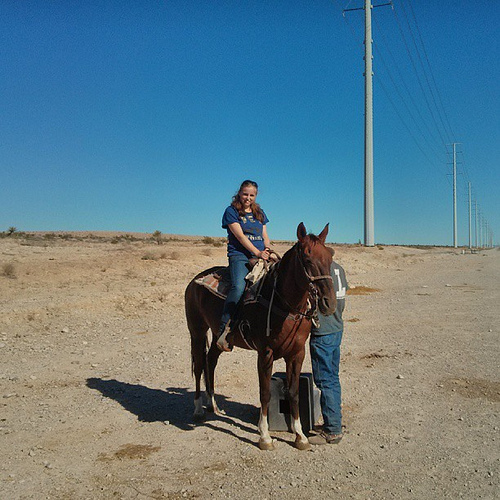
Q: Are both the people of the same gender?
A: No, they are both male and female.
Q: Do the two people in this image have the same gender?
A: No, they are both male and female.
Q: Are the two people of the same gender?
A: No, they are both male and female.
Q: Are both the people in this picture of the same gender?
A: No, they are both male and female.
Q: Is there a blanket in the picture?
A: Yes, there is a blanket.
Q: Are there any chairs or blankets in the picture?
A: Yes, there is a blanket.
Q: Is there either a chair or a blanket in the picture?
A: Yes, there is a blanket.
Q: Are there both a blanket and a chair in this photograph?
A: No, there is a blanket but no chairs.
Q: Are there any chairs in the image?
A: No, there are no chairs.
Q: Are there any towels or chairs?
A: No, there are no chairs or towels.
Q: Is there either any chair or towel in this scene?
A: No, there are no chairs or towels.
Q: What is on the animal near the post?
A: The blanket is on the horse.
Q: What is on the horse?
A: The blanket is on the horse.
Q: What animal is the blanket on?
A: The blanket is on the horse.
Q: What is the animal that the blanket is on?
A: The animal is a horse.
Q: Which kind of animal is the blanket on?
A: The blanket is on the horse.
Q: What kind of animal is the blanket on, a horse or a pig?
A: The blanket is on a horse.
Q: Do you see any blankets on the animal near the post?
A: Yes, there is a blanket on the horse.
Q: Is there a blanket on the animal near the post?
A: Yes, there is a blanket on the horse.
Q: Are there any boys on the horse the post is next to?
A: No, there is a blanket on the horse.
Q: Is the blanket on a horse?
A: Yes, the blanket is on a horse.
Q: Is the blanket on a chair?
A: No, the blanket is on a horse.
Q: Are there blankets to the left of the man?
A: Yes, there is a blanket to the left of the man.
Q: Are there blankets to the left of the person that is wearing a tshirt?
A: Yes, there is a blanket to the left of the man.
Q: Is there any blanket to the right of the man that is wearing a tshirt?
A: No, the blanket is to the left of the man.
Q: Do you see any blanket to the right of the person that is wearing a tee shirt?
A: No, the blanket is to the left of the man.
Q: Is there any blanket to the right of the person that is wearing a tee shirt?
A: No, the blanket is to the left of the man.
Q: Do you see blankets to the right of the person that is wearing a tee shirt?
A: No, the blanket is to the left of the man.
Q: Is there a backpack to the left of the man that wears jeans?
A: No, there is a blanket to the left of the man.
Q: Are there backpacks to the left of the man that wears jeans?
A: No, there is a blanket to the left of the man.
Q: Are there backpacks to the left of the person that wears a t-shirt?
A: No, there is a blanket to the left of the man.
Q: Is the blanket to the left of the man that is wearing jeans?
A: Yes, the blanket is to the left of the man.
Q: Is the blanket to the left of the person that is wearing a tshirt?
A: Yes, the blanket is to the left of the man.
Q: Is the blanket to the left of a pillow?
A: No, the blanket is to the left of the man.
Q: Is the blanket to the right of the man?
A: No, the blanket is to the left of the man.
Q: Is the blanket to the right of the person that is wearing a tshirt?
A: No, the blanket is to the left of the man.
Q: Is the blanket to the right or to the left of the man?
A: The blanket is to the left of the man.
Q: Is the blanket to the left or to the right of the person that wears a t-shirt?
A: The blanket is to the left of the man.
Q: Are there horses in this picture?
A: Yes, there is a horse.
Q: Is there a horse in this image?
A: Yes, there is a horse.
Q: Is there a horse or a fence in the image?
A: Yes, there is a horse.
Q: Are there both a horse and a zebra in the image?
A: No, there is a horse but no zebras.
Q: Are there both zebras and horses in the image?
A: No, there is a horse but no zebras.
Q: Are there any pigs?
A: No, there are no pigs.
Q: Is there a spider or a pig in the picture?
A: No, there are no pigs or spiders.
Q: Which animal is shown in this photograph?
A: The animal is a horse.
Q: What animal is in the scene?
A: The animal is a horse.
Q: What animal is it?
A: The animal is a horse.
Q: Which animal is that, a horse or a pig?
A: That is a horse.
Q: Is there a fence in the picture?
A: No, there are no fences.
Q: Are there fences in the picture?
A: No, there are no fences.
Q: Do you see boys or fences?
A: No, there are no fences or boys.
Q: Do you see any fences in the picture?
A: No, there are no fences.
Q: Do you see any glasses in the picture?
A: No, there are no glasses.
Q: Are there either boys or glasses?
A: No, there are no glasses or boys.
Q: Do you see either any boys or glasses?
A: No, there are no glasses or boys.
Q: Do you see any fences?
A: No, there are no fences.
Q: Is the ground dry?
A: Yes, the ground is dry.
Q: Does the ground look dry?
A: Yes, the ground is dry.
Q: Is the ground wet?
A: No, the ground is dry.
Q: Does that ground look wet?
A: No, the ground is dry.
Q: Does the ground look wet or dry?
A: The ground is dry.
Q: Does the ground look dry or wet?
A: The ground is dry.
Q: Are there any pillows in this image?
A: No, there are no pillows.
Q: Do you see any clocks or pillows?
A: No, there are no pillows or clocks.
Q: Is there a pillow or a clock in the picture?
A: No, there are no pillows or clocks.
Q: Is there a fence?
A: No, there are no fences.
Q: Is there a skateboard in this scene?
A: No, there are no skateboards.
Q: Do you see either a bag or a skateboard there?
A: No, there are no skateboards or bags.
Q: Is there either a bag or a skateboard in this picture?
A: No, there are no skateboards or bags.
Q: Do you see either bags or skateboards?
A: No, there are no skateboards or bags.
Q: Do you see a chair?
A: No, there are no chairs.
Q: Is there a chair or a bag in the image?
A: No, there are no chairs or bags.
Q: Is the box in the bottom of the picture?
A: Yes, the box is in the bottom of the image.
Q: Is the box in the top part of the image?
A: No, the box is in the bottom of the image.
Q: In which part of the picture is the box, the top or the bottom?
A: The box is in the bottom of the image.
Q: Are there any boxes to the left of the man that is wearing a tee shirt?
A: Yes, there is a box to the left of the man.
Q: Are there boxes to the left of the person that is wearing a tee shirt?
A: Yes, there is a box to the left of the man.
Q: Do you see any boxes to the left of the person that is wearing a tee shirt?
A: Yes, there is a box to the left of the man.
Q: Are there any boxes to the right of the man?
A: No, the box is to the left of the man.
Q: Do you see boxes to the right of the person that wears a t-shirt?
A: No, the box is to the left of the man.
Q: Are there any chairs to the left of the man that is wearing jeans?
A: No, there is a box to the left of the man.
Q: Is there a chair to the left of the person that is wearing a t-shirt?
A: No, there is a box to the left of the man.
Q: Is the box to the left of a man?
A: Yes, the box is to the left of a man.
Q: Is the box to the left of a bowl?
A: No, the box is to the left of a man.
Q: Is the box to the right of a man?
A: No, the box is to the left of a man.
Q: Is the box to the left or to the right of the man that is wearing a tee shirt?
A: The box is to the left of the man.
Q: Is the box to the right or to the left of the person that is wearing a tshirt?
A: The box is to the left of the man.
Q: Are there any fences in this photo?
A: No, there are no fences.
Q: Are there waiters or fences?
A: No, there are no fences or waiters.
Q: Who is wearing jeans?
A: The man is wearing jeans.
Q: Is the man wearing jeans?
A: Yes, the man is wearing jeans.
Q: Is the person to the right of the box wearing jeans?
A: Yes, the man is wearing jeans.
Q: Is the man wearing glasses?
A: No, the man is wearing jeans.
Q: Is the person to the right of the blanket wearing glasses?
A: No, the man is wearing jeans.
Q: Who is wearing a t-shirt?
A: The man is wearing a t-shirt.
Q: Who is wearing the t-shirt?
A: The man is wearing a t-shirt.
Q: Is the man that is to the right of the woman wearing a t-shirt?
A: Yes, the man is wearing a t-shirt.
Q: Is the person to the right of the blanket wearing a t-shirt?
A: Yes, the man is wearing a t-shirt.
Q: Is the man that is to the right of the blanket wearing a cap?
A: No, the man is wearing a t-shirt.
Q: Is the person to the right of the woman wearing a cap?
A: No, the man is wearing a t-shirt.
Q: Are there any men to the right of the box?
A: Yes, there is a man to the right of the box.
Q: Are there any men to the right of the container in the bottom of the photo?
A: Yes, there is a man to the right of the box.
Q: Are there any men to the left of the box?
A: No, the man is to the right of the box.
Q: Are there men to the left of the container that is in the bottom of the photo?
A: No, the man is to the right of the box.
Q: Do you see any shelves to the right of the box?
A: No, there is a man to the right of the box.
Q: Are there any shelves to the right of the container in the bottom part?
A: No, there is a man to the right of the box.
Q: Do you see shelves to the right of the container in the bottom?
A: No, there is a man to the right of the box.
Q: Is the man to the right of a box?
A: Yes, the man is to the right of a box.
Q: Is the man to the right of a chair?
A: No, the man is to the right of a box.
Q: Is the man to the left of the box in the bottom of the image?
A: No, the man is to the right of the box.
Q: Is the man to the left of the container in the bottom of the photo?
A: No, the man is to the right of the box.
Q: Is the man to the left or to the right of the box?
A: The man is to the right of the box.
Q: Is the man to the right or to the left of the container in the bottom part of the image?
A: The man is to the right of the box.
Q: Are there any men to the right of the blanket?
A: Yes, there is a man to the right of the blanket.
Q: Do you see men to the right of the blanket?
A: Yes, there is a man to the right of the blanket.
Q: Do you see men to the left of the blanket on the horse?
A: No, the man is to the right of the blanket.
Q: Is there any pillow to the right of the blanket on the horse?
A: No, there is a man to the right of the blanket.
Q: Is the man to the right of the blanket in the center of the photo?
A: Yes, the man is to the right of the blanket.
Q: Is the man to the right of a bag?
A: No, the man is to the right of the blanket.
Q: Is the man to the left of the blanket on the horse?
A: No, the man is to the right of the blanket.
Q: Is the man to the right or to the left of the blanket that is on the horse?
A: The man is to the right of the blanket.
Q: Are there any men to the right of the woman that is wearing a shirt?
A: Yes, there is a man to the right of the woman.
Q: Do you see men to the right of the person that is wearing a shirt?
A: Yes, there is a man to the right of the woman.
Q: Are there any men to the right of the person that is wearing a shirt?
A: Yes, there is a man to the right of the woman.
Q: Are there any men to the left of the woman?
A: No, the man is to the right of the woman.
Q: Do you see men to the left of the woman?
A: No, the man is to the right of the woman.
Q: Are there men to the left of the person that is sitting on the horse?
A: No, the man is to the right of the woman.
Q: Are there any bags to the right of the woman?
A: No, there is a man to the right of the woman.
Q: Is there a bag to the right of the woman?
A: No, there is a man to the right of the woman.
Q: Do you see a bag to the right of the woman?
A: No, there is a man to the right of the woman.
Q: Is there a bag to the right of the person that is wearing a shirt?
A: No, there is a man to the right of the woman.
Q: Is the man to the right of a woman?
A: Yes, the man is to the right of a woman.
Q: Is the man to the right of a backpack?
A: No, the man is to the right of a woman.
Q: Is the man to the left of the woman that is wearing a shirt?
A: No, the man is to the right of the woman.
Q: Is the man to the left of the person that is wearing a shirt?
A: No, the man is to the right of the woman.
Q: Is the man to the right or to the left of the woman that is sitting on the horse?
A: The man is to the right of the woman.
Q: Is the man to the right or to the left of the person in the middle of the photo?
A: The man is to the right of the woman.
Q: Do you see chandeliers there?
A: No, there are no chandeliers.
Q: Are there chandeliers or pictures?
A: No, there are no chandeliers or pictures.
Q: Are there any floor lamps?
A: No, there are no floor lamps.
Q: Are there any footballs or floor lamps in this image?
A: No, there are no floor lamps or footballs.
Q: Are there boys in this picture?
A: No, there are no boys.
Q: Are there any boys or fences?
A: No, there are no boys or fences.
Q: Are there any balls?
A: No, there are no balls.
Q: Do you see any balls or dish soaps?
A: No, there are no balls or dish soaps.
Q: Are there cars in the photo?
A: No, there are no cars.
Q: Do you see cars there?
A: No, there are no cars.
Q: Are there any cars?
A: No, there are no cars.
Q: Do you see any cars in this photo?
A: No, there are no cars.